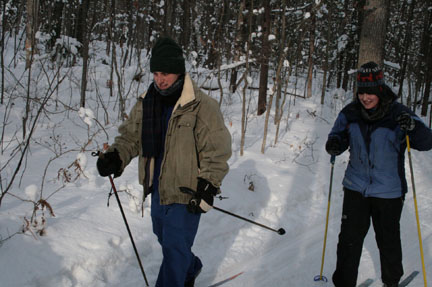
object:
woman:
[325, 59, 432, 286]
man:
[95, 34, 233, 286]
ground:
[0, 27, 432, 286]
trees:
[0, 1, 432, 141]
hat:
[150, 36, 188, 77]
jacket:
[103, 75, 233, 206]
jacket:
[323, 97, 432, 199]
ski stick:
[312, 153, 338, 287]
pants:
[331, 188, 410, 287]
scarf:
[141, 70, 187, 162]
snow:
[89, 87, 113, 103]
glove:
[189, 176, 216, 217]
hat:
[354, 60, 388, 106]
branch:
[48, 94, 111, 142]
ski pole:
[405, 124, 428, 286]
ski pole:
[96, 147, 149, 286]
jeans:
[150, 192, 204, 286]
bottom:
[313, 273, 328, 285]